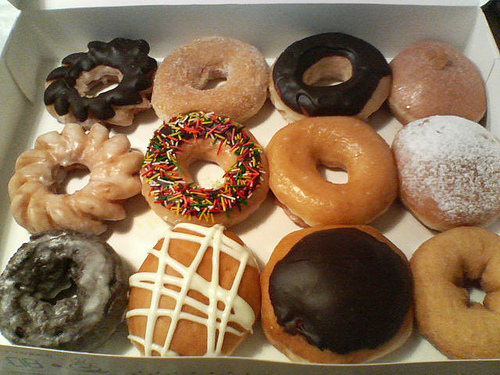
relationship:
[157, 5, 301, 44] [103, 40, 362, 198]
plate with items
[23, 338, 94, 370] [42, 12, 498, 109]
symbols on box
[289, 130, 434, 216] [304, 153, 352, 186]
donut has hole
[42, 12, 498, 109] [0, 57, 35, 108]
box has seam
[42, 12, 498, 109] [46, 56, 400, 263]
box of donuts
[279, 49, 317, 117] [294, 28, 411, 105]
chocolate on donut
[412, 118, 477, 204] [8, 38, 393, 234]
donut has items